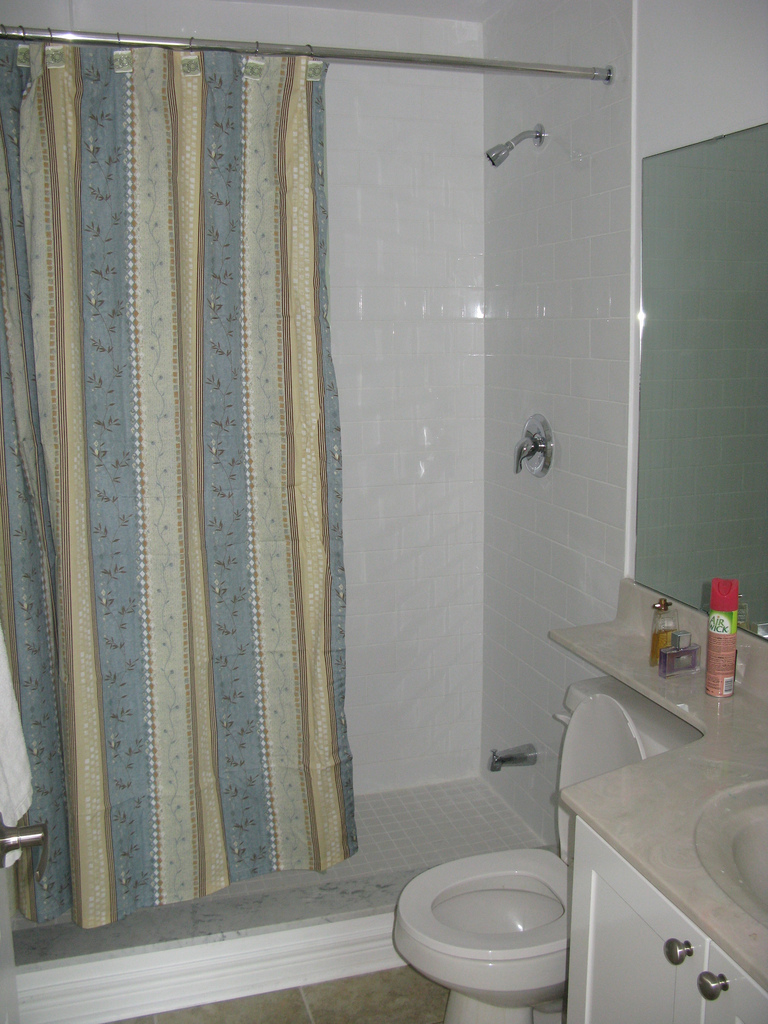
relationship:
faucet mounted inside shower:
[506, 395, 557, 486] [3, 2, 639, 1021]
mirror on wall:
[633, 118, 767, 570] [515, 43, 766, 710]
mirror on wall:
[633, 118, 768, 641] [616, 9, 766, 696]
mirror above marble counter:
[633, 118, 768, 641] [627, 775, 755, 858]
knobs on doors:
[651, 919, 744, 1008] [555, 806, 760, 1021]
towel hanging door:
[0, 577, 40, 826] [0, 559, 37, 1021]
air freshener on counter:
[700, 567, 744, 709] [535, 559, 759, 1021]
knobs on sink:
[695, 959, 733, 1002] [643, 731, 767, 966]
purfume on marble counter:
[634, 587, 684, 680] [627, 775, 755, 858]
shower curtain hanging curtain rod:
[17, 31, 340, 938] [1, 19, 619, 88]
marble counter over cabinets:
[538, 636, 722, 887] [567, 798, 720, 999]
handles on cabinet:
[571, 863, 742, 1022] [568, 811, 768, 1019]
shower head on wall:
[452, 100, 535, 189] [437, 114, 650, 573]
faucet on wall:
[487, 395, 558, 552] [452, 118, 629, 648]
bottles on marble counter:
[617, 557, 753, 698] [536, 599, 762, 878]